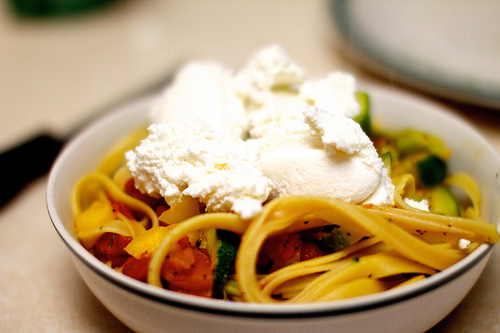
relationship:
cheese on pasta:
[164, 77, 353, 197] [367, 243, 412, 265]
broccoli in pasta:
[407, 149, 441, 187] [367, 243, 412, 265]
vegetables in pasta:
[210, 239, 238, 299] [367, 243, 412, 265]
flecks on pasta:
[338, 239, 389, 287] [367, 243, 412, 265]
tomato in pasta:
[149, 246, 208, 289] [367, 243, 412, 265]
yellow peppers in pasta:
[120, 212, 183, 257] [367, 243, 412, 265]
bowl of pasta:
[429, 295, 464, 306] [367, 243, 412, 265]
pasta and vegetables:
[367, 243, 412, 265] [89, 200, 261, 293]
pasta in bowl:
[367, 243, 412, 265] [429, 295, 464, 306]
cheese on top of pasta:
[164, 77, 353, 197] [367, 243, 412, 265]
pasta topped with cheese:
[367, 243, 412, 265] [164, 77, 353, 197]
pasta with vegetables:
[367, 243, 412, 265] [89, 200, 261, 293]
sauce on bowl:
[464, 137, 495, 167] [429, 295, 464, 306]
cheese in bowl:
[164, 77, 353, 197] [429, 295, 464, 306]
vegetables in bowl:
[89, 200, 261, 293] [429, 295, 464, 306]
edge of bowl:
[79, 139, 86, 145] [429, 295, 464, 306]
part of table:
[107, 16, 127, 31] [190, 19, 262, 32]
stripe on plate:
[418, 279, 442, 286] [378, 37, 452, 75]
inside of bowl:
[110, 124, 135, 138] [429, 295, 464, 306]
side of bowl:
[101, 294, 143, 319] [429, 295, 464, 306]